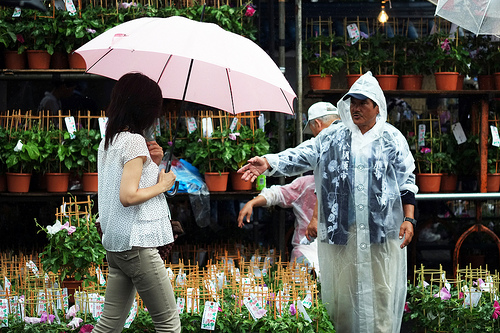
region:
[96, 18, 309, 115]
Pink umbrella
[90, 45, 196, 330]
Woman holding a pink umbrella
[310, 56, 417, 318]
Man wearing a rain parka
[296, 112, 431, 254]
Man wearing a Hawaiian shirt under his parka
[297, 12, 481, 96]
Plants line the back of the picture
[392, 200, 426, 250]
Man wearing a watch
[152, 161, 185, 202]
Woman holding umbrella with right hand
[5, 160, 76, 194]
Plants sitting in pots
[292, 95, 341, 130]
Man in a white hat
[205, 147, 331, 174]
Man extending his hand to a woman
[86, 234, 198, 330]
Pants on a woman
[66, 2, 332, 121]
Pink umbrella above a woman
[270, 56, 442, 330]
Man in a plastic suit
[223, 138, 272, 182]
Hand in the air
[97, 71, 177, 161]
Dark hair on a woman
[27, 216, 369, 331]
Plants on the ground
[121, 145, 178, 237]
Arm holding an umbrella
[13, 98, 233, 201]
Plants on a shelf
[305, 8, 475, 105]
plants on display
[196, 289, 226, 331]
Tag on a plant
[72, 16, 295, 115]
a pink umbrella canopy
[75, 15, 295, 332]
a girl walking in the rain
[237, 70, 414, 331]
a man wearing a clear rain coat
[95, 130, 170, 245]
the girl is wearing a white blouse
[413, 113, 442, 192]
a plant in a clay pot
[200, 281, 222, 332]
plants with identification tags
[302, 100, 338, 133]
a man with a white baseball hat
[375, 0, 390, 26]
a light bulb hanging from the ceiling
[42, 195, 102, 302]
a plant on a wood trellis frame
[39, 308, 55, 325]
a pink flower in the pot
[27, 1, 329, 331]
lady holding an umbrella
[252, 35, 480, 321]
man wearing rain coat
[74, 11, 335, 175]
the umbrella is pink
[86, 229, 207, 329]
woman's pants are gray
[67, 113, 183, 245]
woman's shirt is white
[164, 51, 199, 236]
handle of umbrella is black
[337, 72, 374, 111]
man is wearing a hat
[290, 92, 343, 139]
man's hat is white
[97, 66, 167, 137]
woman's hair is black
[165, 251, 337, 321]
plants have yellow sticks in them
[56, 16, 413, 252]
the umbrella is pink